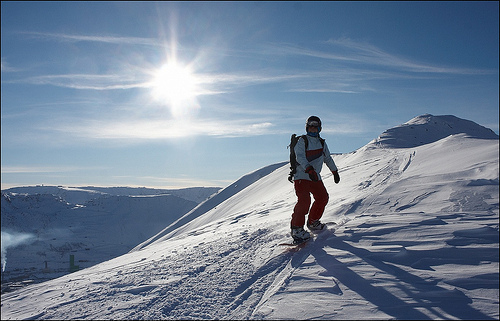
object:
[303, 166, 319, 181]
gloves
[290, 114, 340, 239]
man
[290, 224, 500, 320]
reflection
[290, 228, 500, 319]
shadow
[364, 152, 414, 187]
tracks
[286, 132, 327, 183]
backpack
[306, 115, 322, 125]
hat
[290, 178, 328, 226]
red pants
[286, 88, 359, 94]
clouds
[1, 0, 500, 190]
sky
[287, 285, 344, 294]
marks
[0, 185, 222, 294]
mountain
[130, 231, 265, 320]
tracks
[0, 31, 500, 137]
smoke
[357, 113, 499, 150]
peak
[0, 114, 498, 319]
mountain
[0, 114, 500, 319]
snow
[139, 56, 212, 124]
sun